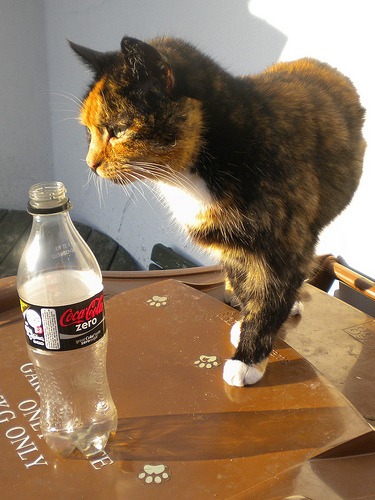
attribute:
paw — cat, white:
[227, 303, 253, 348]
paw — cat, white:
[223, 334, 271, 396]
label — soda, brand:
[15, 268, 105, 351]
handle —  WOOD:
[302, 253, 374, 321]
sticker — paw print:
[134, 457, 170, 485]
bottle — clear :
[14, 174, 139, 491]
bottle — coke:
[17, 167, 133, 462]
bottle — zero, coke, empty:
[14, 177, 111, 468]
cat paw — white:
[220, 357, 263, 387]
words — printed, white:
[3, 369, 113, 486]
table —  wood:
[2, 208, 145, 279]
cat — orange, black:
[22, 22, 293, 220]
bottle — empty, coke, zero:
[13, 181, 120, 458]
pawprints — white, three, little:
[136, 463, 172, 484]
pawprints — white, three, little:
[194, 353, 219, 368]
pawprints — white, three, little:
[146, 292, 169, 309]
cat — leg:
[67, 35, 364, 386]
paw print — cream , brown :
[145, 289, 169, 310]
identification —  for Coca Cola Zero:
[58, 296, 105, 328]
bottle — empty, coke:
[15, 161, 115, 407]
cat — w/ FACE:
[88, 52, 355, 301]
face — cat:
[71, 32, 202, 187]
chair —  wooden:
[19, 152, 367, 435]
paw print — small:
[136, 462, 173, 485]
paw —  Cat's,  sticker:
[218, 356, 273, 388]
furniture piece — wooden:
[2, 250, 372, 498]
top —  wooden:
[2, 248, 370, 497]